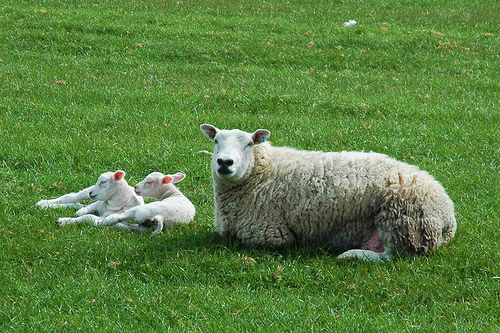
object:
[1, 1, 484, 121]
field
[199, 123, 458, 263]
sheep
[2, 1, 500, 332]
grass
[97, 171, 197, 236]
sheep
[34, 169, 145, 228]
sheep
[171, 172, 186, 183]
ears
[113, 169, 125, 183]
ear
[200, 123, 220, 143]
ears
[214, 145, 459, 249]
fur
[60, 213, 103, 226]
feets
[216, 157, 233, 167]
nose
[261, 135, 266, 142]
tag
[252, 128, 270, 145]
ear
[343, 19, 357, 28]
plant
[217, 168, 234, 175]
mouth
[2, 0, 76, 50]
part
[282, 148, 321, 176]
part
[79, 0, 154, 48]
part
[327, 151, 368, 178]
part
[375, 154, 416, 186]
part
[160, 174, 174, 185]
ear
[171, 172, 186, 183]
ear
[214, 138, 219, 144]
eye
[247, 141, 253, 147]
eye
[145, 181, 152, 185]
eye